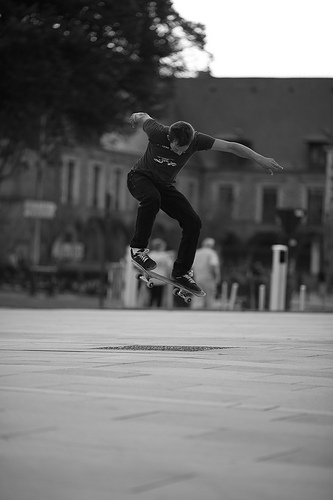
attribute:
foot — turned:
[130, 248, 156, 268]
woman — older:
[143, 234, 173, 307]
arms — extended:
[127, 111, 284, 176]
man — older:
[115, 105, 289, 275]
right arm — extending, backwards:
[125, 108, 167, 144]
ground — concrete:
[25, 324, 331, 458]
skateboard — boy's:
[130, 256, 213, 309]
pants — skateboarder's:
[121, 172, 207, 270]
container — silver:
[266, 242, 295, 311]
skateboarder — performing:
[110, 101, 292, 306]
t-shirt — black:
[132, 118, 213, 186]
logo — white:
[149, 152, 178, 167]